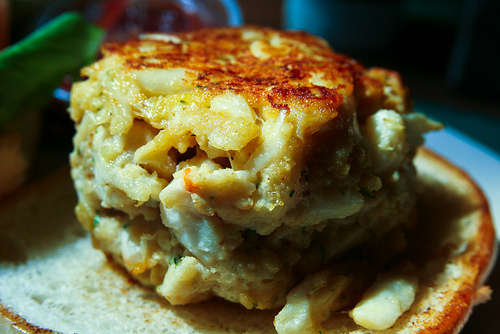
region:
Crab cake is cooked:
[56, 10, 428, 325]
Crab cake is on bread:
[4, 17, 496, 332]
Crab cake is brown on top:
[65, 5, 408, 135]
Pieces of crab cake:
[267, 245, 423, 331]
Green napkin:
[0, 7, 106, 123]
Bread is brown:
[412, 143, 497, 326]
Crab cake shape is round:
[58, 20, 428, 327]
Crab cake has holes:
[73, 90, 268, 262]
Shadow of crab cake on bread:
[394, 160, 498, 314]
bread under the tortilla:
[0, 92, 490, 327]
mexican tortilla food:
[65, 16, 430, 319]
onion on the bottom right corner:
[256, 250, 431, 330]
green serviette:
[1, 2, 108, 99]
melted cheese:
[145, 115, 270, 185]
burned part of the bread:
[395, 155, 491, 330]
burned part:
[72, 13, 387, 128]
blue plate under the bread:
[158, 107, 495, 318]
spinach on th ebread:
[45, 195, 208, 270]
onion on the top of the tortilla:
[136, 58, 208, 100]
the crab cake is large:
[76, 25, 421, 298]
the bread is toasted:
[0, 135, 496, 330]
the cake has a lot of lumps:
[70, 25, 415, 306]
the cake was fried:
[71, 30, 416, 305]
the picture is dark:
[1, 0, 499, 330]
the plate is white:
[417, 122, 497, 239]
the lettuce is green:
[1, 12, 103, 105]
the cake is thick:
[70, 27, 422, 312]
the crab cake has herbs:
[72, 25, 426, 301]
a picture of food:
[0, 0, 497, 332]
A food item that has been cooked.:
[41, 26, 412, 308]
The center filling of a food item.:
[86, 160, 271, 240]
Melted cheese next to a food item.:
[303, 265, 418, 331]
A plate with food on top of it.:
[366, 168, 484, 331]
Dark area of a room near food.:
[422, 0, 478, 66]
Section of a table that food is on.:
[453, 103, 474, 138]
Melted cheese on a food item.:
[98, 82, 233, 142]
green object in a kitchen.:
[16, 22, 109, 88]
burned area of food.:
[190, 56, 330, 131]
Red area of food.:
[160, 141, 255, 211]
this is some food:
[88, 40, 444, 292]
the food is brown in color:
[228, 44, 325, 91]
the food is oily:
[212, 35, 296, 75]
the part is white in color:
[165, 185, 252, 250]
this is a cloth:
[28, 36, 58, 70]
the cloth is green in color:
[24, 40, 48, 76]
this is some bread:
[26, 256, 77, 316]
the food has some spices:
[166, 180, 315, 247]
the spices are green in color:
[169, 252, 181, 266]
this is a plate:
[462, 146, 481, 169]